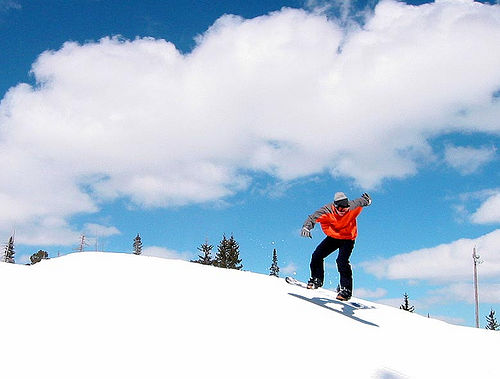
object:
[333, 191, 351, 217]
head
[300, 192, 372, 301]
man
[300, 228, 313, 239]
hand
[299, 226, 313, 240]
glove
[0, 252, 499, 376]
ground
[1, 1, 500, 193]
sky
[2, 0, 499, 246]
cloud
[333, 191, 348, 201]
hat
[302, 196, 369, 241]
coat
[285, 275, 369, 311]
snowboard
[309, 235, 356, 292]
pants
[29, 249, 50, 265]
tree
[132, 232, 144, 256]
tree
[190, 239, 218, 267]
tree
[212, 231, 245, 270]
tree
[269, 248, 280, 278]
tree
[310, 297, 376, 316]
shadow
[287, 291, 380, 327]
shadow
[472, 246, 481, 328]
pole